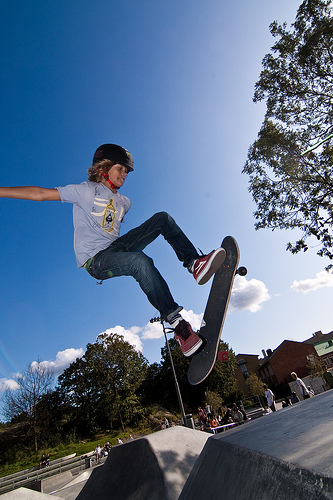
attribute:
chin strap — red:
[96, 165, 121, 191]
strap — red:
[100, 171, 117, 193]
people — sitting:
[195, 406, 238, 421]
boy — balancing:
[48, 138, 223, 353]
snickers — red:
[169, 246, 226, 357]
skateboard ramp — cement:
[175, 389, 330, 499]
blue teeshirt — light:
[55, 181, 127, 269]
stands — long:
[0, 404, 264, 492]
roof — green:
[307, 336, 331, 356]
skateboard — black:
[190, 228, 253, 378]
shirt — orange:
[39, 176, 149, 266]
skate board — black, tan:
[183, 238, 245, 399]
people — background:
[193, 401, 248, 423]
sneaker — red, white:
[169, 317, 204, 356]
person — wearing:
[208, 412, 217, 429]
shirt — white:
[258, 390, 277, 408]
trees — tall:
[161, 327, 238, 410]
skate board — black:
[184, 217, 243, 392]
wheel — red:
[237, 264, 250, 278]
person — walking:
[62, 136, 247, 381]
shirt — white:
[48, 165, 117, 250]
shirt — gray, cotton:
[71, 182, 139, 270]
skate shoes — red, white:
[169, 247, 228, 356]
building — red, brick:
[259, 334, 329, 396]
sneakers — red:
[174, 228, 239, 376]